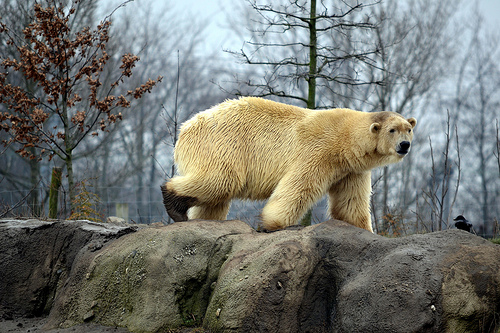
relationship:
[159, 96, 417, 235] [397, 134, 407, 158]
bear with nose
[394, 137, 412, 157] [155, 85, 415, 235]
black nose on a polar bear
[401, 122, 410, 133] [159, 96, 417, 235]
eyes of a bear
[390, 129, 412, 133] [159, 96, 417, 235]
eyes of a bear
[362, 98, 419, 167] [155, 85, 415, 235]
head of a polar bear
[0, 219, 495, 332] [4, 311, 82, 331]
boulder on ground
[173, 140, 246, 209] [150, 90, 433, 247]
leg pf polar bear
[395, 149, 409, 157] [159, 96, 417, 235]
mouth of bear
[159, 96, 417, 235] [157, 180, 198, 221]
bear with paw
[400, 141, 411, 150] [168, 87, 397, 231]
black nose on bear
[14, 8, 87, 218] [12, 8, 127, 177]
tree with leaves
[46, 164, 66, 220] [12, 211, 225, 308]
post behind rock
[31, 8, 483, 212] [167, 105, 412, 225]
forest behind bear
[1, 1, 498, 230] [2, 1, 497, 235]
sky behind trees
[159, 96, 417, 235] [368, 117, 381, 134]
bear have ears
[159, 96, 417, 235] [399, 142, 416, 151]
bear has nose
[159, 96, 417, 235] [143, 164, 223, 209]
bear has paws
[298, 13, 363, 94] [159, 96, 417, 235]
bare tree behind bear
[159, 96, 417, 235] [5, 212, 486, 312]
bear on rocks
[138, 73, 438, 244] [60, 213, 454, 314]
bear on boulder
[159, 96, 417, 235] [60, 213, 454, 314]
bear on boulder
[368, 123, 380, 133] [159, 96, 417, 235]
ear on bear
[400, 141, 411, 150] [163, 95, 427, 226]
black nose on bear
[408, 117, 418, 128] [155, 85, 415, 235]
ear of polar bear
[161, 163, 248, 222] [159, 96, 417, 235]
leg of bear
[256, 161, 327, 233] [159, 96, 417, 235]
leg of bear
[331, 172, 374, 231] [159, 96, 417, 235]
leg of bear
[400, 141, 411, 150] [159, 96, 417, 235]
black nose of bear